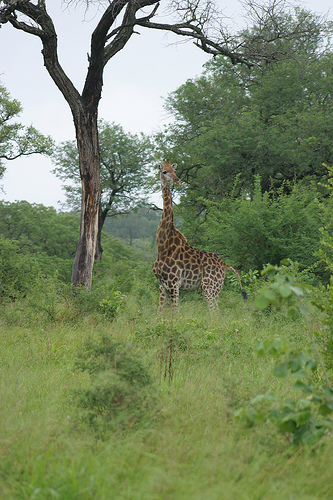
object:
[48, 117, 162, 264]
small tree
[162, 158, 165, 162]
horn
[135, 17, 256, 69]
branch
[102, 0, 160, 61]
branch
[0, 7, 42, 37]
branch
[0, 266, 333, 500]
ground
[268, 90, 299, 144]
leaves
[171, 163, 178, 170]
ear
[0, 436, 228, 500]
grasses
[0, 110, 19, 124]
branch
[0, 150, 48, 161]
branch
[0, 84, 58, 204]
tree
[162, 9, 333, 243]
tree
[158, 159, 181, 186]
head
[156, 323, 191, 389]
foilage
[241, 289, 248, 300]
turf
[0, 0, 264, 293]
tall tree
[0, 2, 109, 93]
sky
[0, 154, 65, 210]
sky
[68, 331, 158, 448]
shrub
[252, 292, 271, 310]
leaves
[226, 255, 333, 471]
shrub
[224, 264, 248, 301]
tail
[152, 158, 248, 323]
giraffe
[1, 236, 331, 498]
field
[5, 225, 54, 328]
foliage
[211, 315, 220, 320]
back feet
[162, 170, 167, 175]
eye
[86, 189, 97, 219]
bark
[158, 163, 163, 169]
ear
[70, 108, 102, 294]
tree trunk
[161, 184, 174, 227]
neck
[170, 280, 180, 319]
leg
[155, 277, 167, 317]
leg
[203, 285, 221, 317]
leg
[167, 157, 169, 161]
horn